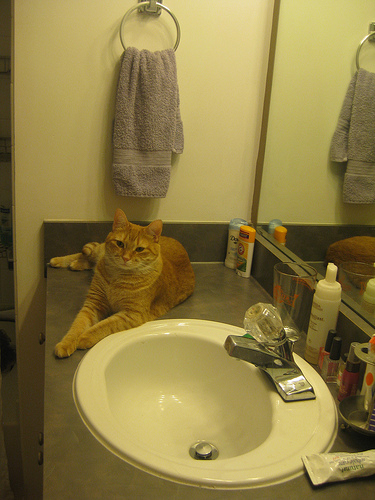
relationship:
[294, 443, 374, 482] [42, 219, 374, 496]
toothpaste tube on counter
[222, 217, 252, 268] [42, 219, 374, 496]
deodorant on counter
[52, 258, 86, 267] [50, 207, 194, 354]
leg of cat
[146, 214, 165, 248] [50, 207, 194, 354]
ear on cat